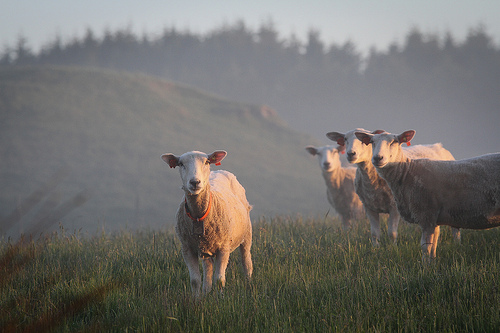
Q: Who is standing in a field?
A: Four goats.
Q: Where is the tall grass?
A: In a field.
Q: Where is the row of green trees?
A: Behind the hill.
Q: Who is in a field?
A: A goat.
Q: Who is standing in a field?
A: A white goat.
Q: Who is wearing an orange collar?
A: A sheep.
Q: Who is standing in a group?
A: Three sheep.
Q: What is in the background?
A: Trees.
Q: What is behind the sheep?
A: A hill.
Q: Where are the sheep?
A: In a field.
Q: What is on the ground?
A: Grass.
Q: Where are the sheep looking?
A: At the camera.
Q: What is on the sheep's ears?
A: Tags.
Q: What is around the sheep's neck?
A: A collar.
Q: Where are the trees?
A: Behind the hill.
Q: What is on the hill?
A: Grass.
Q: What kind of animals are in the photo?
A: Sheep.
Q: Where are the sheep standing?
A: On grass.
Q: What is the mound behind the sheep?
A: A hill.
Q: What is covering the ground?
A: Tall grass.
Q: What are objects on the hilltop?
A: Trees.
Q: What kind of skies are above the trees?
A: Gray.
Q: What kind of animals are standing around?
A: Four sheep.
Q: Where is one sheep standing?
A: Alone.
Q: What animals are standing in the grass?
A: Four sheep.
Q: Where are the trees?
A: In the distance.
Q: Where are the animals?
A: In the field.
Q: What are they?
A: Sheep.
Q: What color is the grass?
A: Green.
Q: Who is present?
A: Nobody.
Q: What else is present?
A: Grass.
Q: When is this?
A: Daytime.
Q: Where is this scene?
A: Outdoor in a mountainous region.